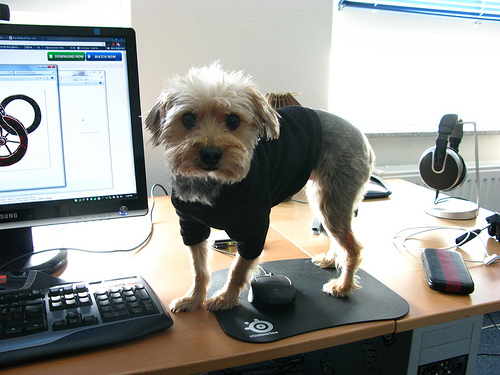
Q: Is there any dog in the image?
A: Yes, there is a dog.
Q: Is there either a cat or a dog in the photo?
A: Yes, there is a dog.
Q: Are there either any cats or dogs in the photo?
A: Yes, there is a dog.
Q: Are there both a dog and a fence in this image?
A: No, there is a dog but no fences.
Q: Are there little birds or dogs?
A: Yes, there is a little dog.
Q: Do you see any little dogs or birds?
A: Yes, there is a little dog.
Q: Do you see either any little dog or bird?
A: Yes, there is a little dog.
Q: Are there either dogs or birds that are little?
A: Yes, the dog is little.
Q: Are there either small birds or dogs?
A: Yes, there is a small dog.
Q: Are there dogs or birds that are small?
A: Yes, the dog is small.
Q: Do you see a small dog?
A: Yes, there is a small dog.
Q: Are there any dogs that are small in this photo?
A: Yes, there is a small dog.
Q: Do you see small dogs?
A: Yes, there is a small dog.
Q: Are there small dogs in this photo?
A: Yes, there is a small dog.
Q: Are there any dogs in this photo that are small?
A: Yes, there is a dog that is small.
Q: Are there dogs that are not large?
A: Yes, there is a small dog.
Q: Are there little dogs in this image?
A: Yes, there is a little dog.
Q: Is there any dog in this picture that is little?
A: Yes, there is a dog that is little.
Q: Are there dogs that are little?
A: Yes, there is a dog that is little.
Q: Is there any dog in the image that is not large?
A: Yes, there is a little dog.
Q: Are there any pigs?
A: No, there are no pigs.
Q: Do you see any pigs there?
A: No, there are no pigs.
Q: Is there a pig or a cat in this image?
A: No, there are no pigs or cats.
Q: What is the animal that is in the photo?
A: The animal is a dog.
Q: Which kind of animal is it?
A: The animal is a dog.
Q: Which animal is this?
A: This is a dog.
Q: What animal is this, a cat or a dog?
A: This is a dog.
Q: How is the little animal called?
A: The animal is a dog.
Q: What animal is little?
A: The animal is a dog.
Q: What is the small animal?
A: The animal is a dog.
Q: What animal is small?
A: The animal is a dog.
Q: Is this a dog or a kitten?
A: This is a dog.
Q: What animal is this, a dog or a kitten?
A: This is a dog.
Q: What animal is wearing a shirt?
A: The dog is wearing a shirt.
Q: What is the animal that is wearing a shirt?
A: The animal is a dog.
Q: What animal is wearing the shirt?
A: The animal is a dog.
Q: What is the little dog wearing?
A: The dog is wearing a shirt.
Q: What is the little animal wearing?
A: The dog is wearing a shirt.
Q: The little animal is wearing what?
A: The dog is wearing a shirt.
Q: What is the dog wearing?
A: The dog is wearing a shirt.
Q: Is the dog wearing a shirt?
A: Yes, the dog is wearing a shirt.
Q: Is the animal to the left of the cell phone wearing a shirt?
A: Yes, the dog is wearing a shirt.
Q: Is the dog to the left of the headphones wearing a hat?
A: No, the dog is wearing a shirt.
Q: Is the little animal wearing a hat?
A: No, the dog is wearing a shirt.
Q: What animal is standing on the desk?
A: The dog is standing on the desk.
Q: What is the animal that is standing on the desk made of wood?
A: The animal is a dog.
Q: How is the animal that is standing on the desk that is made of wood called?
A: The animal is a dog.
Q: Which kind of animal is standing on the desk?
A: The animal is a dog.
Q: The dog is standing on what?
A: The dog is standing on the desk.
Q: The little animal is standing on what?
A: The dog is standing on the desk.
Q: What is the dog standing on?
A: The dog is standing on the desk.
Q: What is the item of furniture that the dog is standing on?
A: The piece of furniture is a desk.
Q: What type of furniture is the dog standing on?
A: The dog is standing on the desk.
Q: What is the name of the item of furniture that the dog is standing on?
A: The piece of furniture is a desk.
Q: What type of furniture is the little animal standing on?
A: The dog is standing on the desk.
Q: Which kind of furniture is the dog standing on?
A: The dog is standing on the desk.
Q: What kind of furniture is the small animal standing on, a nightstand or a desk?
A: The dog is standing on a desk.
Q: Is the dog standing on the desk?
A: Yes, the dog is standing on the desk.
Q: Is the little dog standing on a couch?
A: No, the dog is standing on the desk.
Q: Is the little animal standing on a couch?
A: No, the dog is standing on the desk.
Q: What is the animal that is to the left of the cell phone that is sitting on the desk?
A: The animal is a dog.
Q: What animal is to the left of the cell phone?
A: The animal is a dog.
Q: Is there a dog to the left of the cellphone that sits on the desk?
A: Yes, there is a dog to the left of the cellphone.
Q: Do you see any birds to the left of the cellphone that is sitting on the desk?
A: No, there is a dog to the left of the cell phone.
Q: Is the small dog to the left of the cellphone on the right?
A: Yes, the dog is to the left of the cellphone.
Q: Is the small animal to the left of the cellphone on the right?
A: Yes, the dog is to the left of the cellphone.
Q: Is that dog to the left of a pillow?
A: No, the dog is to the left of the cellphone.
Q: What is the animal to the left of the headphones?
A: The animal is a dog.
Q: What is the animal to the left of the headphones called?
A: The animal is a dog.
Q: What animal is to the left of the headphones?
A: The animal is a dog.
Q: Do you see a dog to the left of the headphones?
A: Yes, there is a dog to the left of the headphones.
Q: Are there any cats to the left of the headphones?
A: No, there is a dog to the left of the headphones.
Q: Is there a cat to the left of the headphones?
A: No, there is a dog to the left of the headphones.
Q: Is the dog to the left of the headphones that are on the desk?
A: Yes, the dog is to the left of the headphones.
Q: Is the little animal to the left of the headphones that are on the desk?
A: Yes, the dog is to the left of the headphones.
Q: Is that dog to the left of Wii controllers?
A: No, the dog is to the left of the headphones.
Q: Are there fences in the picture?
A: No, there are no fences.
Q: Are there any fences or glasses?
A: No, there are no fences or glasses.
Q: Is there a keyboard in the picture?
A: Yes, there is a keyboard.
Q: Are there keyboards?
A: Yes, there is a keyboard.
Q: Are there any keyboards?
A: Yes, there is a keyboard.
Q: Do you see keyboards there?
A: Yes, there is a keyboard.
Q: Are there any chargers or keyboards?
A: Yes, there is a keyboard.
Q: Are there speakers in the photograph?
A: No, there are no speakers.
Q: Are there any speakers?
A: No, there are no speakers.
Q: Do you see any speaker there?
A: No, there are no speakers.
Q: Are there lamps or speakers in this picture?
A: No, there are no speakers or lamps.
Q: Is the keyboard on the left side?
A: Yes, the keyboard is on the left of the image.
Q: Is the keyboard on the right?
A: No, the keyboard is on the left of the image.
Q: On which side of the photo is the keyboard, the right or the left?
A: The keyboard is on the left of the image.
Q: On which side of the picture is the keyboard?
A: The keyboard is on the left of the image.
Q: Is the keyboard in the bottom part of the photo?
A: Yes, the keyboard is in the bottom of the image.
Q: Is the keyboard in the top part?
A: No, the keyboard is in the bottom of the image.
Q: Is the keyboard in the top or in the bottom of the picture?
A: The keyboard is in the bottom of the image.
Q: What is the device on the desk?
A: The device is a keyboard.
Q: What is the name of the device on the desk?
A: The device is a keyboard.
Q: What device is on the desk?
A: The device is a keyboard.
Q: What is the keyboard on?
A: The keyboard is on the desk.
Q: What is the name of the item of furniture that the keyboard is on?
A: The piece of furniture is a desk.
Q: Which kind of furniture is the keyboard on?
A: The keyboard is on the desk.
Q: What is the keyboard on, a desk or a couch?
A: The keyboard is on a desk.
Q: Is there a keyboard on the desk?
A: Yes, there is a keyboard on the desk.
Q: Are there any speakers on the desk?
A: No, there is a keyboard on the desk.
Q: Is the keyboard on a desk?
A: Yes, the keyboard is on a desk.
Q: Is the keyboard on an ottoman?
A: No, the keyboard is on a desk.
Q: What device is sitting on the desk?
A: The device is a keyboard.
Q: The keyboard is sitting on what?
A: The keyboard is sitting on the desk.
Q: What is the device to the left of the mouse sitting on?
A: The keyboard is sitting on the desk.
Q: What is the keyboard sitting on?
A: The keyboard is sitting on the desk.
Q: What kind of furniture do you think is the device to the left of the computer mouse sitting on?
A: The keyboard is sitting on the desk.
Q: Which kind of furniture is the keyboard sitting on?
A: The keyboard is sitting on the desk.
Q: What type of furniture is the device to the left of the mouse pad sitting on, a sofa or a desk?
A: The keyboard is sitting on a desk.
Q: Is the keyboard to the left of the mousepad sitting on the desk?
A: Yes, the keyboard is sitting on the desk.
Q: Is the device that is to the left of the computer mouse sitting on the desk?
A: Yes, the keyboard is sitting on the desk.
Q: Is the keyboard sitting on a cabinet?
A: No, the keyboard is sitting on the desk.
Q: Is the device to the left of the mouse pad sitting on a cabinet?
A: No, the keyboard is sitting on the desk.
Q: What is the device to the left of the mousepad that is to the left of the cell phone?
A: The device is a keyboard.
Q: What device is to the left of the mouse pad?
A: The device is a keyboard.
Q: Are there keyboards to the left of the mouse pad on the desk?
A: Yes, there is a keyboard to the left of the mousepad.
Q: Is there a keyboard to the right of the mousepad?
A: No, the keyboard is to the left of the mousepad.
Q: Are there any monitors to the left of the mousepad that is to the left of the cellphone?
A: No, there is a keyboard to the left of the mouse pad.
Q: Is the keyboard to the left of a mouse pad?
A: Yes, the keyboard is to the left of a mouse pad.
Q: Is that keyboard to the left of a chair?
A: No, the keyboard is to the left of a mouse pad.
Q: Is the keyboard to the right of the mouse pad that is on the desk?
A: No, the keyboard is to the left of the mouse pad.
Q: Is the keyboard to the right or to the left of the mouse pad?
A: The keyboard is to the left of the mouse pad.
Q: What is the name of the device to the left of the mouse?
A: The device is a keyboard.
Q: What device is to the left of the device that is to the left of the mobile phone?
A: The device is a keyboard.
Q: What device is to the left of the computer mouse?
A: The device is a keyboard.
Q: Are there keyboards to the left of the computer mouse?
A: Yes, there is a keyboard to the left of the computer mouse.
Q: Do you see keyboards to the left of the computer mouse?
A: Yes, there is a keyboard to the left of the computer mouse.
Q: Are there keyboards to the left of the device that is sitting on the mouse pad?
A: Yes, there is a keyboard to the left of the computer mouse.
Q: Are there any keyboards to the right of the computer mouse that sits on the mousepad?
A: No, the keyboard is to the left of the computer mouse.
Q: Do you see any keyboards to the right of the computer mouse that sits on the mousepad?
A: No, the keyboard is to the left of the computer mouse.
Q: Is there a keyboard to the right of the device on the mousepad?
A: No, the keyboard is to the left of the computer mouse.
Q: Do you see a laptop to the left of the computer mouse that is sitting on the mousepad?
A: No, there is a keyboard to the left of the mouse.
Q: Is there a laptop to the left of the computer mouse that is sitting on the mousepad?
A: No, there is a keyboard to the left of the mouse.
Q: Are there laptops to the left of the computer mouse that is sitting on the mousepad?
A: No, there is a keyboard to the left of the mouse.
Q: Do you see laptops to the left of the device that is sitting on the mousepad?
A: No, there is a keyboard to the left of the mouse.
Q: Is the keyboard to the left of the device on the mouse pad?
A: Yes, the keyboard is to the left of the computer mouse.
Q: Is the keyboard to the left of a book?
A: No, the keyboard is to the left of the computer mouse.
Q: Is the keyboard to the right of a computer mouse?
A: No, the keyboard is to the left of a computer mouse.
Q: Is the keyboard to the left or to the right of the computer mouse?
A: The keyboard is to the left of the computer mouse.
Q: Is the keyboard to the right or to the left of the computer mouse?
A: The keyboard is to the left of the computer mouse.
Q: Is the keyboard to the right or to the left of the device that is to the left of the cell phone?
A: The keyboard is to the left of the computer mouse.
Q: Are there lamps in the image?
A: No, there are no lamps.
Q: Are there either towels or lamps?
A: No, there are no lamps or towels.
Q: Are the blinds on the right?
A: Yes, the blinds are on the right of the image.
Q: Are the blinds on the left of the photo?
A: No, the blinds are on the right of the image.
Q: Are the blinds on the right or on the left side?
A: The blinds are on the right of the image.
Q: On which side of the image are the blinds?
A: The blinds are on the right of the image.